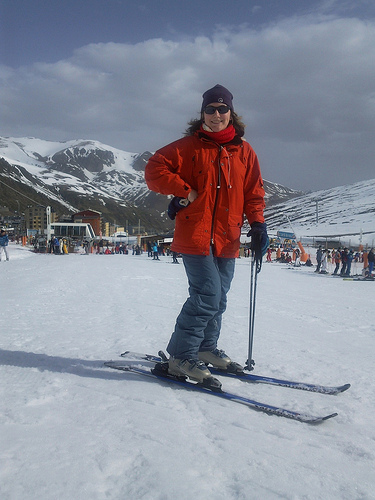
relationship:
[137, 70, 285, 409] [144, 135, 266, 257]
people has jacket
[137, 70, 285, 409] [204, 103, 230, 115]
people wearing sunglasses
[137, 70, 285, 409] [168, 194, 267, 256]
people wearing gloves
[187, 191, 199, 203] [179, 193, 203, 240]
hand in pocket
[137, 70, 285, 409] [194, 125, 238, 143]
people wearing scarf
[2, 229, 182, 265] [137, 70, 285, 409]
people behind people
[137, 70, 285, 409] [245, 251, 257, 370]
people holding poles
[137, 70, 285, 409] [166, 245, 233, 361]
people wearing pants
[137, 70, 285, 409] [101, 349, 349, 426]
people has skis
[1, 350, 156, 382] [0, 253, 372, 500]
shadow on snow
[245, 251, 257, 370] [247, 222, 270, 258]
poles in hand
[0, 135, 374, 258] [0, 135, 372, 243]
mountains with snow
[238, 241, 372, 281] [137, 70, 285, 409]
people behind people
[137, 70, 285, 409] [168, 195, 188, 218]
people has glove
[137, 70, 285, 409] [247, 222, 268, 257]
people has glove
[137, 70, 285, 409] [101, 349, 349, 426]
people on skis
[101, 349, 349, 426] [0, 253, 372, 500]
skis in snow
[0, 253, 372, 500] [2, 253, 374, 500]
snow on ground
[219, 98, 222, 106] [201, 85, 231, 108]
design on hat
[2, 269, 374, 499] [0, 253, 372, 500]
tracks in snow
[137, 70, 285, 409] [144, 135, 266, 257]
people in jacket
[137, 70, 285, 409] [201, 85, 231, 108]
people wears hat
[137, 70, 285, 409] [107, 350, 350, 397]
people with ski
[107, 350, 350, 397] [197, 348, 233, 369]
ski on foot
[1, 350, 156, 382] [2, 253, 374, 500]
shadow on ground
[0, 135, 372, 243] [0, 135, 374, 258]
snow on mountains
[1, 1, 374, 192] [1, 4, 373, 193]
clouds in sky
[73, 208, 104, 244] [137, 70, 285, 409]
building behind people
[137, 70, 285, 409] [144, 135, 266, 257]
people wearing jacket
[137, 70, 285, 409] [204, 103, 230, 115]
people wears sunglasses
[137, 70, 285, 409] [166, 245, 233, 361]
people wears pants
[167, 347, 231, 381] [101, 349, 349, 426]
boots on skis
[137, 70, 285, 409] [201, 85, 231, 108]
people wearing hat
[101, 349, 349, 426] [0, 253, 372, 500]
skis on snow